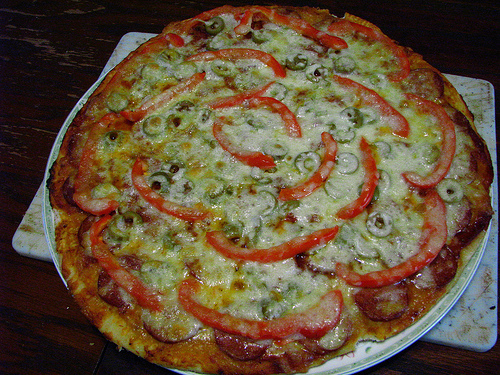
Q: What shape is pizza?
A: Round.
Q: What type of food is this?
A: Pizza.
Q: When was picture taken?
A: After pizza was cooked.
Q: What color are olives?
A: Black.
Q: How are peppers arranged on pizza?
A: In circles.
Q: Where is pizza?
A: On pan.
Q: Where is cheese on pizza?
A: Top of pizza.